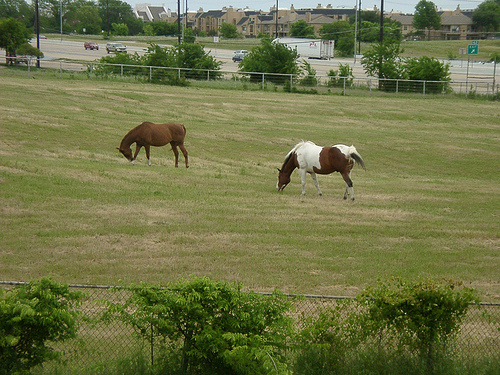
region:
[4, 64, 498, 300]
the grassy field inside the fences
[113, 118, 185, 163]
the brown horse in the field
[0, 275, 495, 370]
the fence closer to the photographer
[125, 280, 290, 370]
a tree by the fence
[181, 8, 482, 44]
a line of houses that are behind the field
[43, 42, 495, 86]
the street with traffic on it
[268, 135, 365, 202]
the brown and white horse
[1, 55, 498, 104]
the other part of the fence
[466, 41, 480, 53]
the sign next to the street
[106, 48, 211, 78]
some more bushes next to the fence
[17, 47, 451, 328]
A photo of two horses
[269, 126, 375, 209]
This horse is brown and white in color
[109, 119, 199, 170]
This horse is brown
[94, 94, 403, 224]
The horses are grazing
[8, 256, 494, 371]
A fence keeps the horses inside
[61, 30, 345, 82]
A highway is nearby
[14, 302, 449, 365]
Bushes are growing along the fence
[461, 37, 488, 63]
An exit sign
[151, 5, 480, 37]
A community is in the background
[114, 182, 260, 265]
The grass is short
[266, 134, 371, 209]
brown and white horse in pasture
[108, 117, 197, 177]
brown horse in pasture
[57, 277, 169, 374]
metal chain link fence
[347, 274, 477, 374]
small green shrub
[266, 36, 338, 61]
heavy duty truck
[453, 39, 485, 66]
green highway exit sign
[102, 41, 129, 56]
beige pickup truck on highway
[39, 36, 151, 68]
highway with passenger vehicles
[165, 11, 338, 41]
brown apartment complex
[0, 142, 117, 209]
green and brown grass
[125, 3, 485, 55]
A suburb.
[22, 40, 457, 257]
Two horses are in a field.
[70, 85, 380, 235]
The horses are grazing.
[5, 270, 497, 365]
Plants are growing on the chain-link fence.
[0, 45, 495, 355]
The field is enclosed by a fence.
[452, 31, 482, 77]
A green street sign.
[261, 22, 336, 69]
A white semi-truck.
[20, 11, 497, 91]
Vehicles on a highway.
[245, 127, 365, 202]
The horse is brown and white.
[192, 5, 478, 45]
The buildings have dark colored roofs.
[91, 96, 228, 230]
Brown horse standing in grass.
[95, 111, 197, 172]
Brown horse bending over.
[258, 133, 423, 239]
Brown and white horse standing in field.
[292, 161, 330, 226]
Horse's front legs are white.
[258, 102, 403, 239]
Horse is brown and white.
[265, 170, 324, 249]
Horse bending down eating grass.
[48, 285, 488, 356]
Green bushes on fence.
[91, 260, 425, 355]
Chain link fence around horses.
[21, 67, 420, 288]
Horses inside of fenced in area.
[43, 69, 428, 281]
Grass is green and brown.